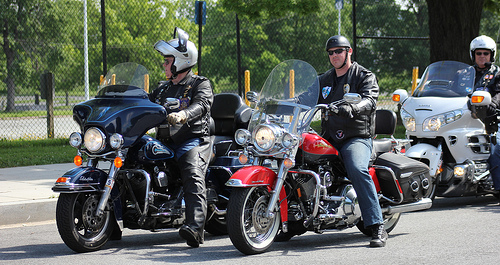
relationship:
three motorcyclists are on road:
[140, 28, 499, 260] [4, 167, 500, 261]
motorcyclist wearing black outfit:
[281, 27, 403, 253] [270, 62, 385, 151]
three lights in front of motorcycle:
[60, 124, 130, 160] [46, 55, 272, 255]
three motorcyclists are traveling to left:
[140, 28, 499, 260] [13, 35, 71, 185]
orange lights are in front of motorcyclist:
[63, 156, 126, 168] [112, 11, 227, 261]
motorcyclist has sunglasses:
[281, 27, 403, 253] [325, 47, 347, 57]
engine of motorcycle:
[299, 159, 345, 208] [214, 51, 441, 251]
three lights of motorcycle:
[60, 124, 130, 160] [46, 55, 272, 255]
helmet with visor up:
[148, 24, 210, 79] [167, 26, 191, 52]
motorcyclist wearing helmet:
[281, 27, 403, 253] [318, 33, 361, 52]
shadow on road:
[0, 239, 120, 262] [4, 167, 500, 261]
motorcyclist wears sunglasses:
[447, 29, 500, 212] [474, 50, 491, 61]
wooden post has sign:
[43, 69, 54, 140] [32, 72, 61, 101]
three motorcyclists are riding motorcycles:
[140, 28, 499, 260] [51, 53, 495, 264]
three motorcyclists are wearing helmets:
[140, 28, 499, 260] [148, 25, 498, 76]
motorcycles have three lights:
[51, 53, 495, 264] [60, 124, 130, 160]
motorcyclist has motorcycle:
[281, 27, 403, 253] [214, 51, 441, 251]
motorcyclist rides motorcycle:
[112, 11, 227, 261] [46, 55, 272, 255]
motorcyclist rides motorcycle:
[447, 29, 500, 212] [387, 59, 499, 213]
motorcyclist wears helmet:
[281, 27, 403, 253] [318, 33, 361, 52]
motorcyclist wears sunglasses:
[281, 27, 403, 253] [325, 47, 347, 57]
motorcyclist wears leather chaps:
[281, 27, 403, 253] [252, 63, 389, 147]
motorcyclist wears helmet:
[112, 11, 227, 261] [148, 24, 210, 79]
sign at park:
[190, 1, 212, 26] [2, 2, 499, 114]